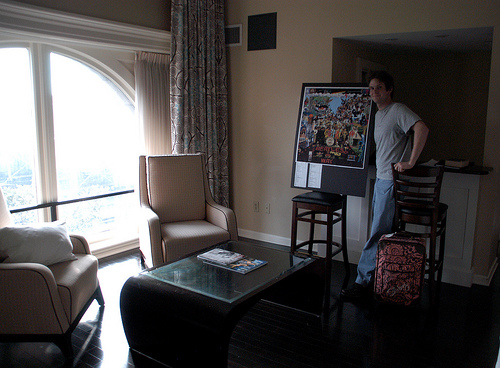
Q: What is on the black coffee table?
A: Glass top.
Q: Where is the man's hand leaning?
A: On the tall dark brown bar stool.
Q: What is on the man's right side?
A: Board with h picture on it.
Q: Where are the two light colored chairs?
A: On either side of the window.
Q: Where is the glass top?
A: On the coffee table.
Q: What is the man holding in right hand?
A: Piece of art.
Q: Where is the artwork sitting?
A: Left bar stool.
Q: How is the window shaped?
A: Semi-circle.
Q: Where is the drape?
A: Behind the right tan chair.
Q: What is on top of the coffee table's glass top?
A: Magazines.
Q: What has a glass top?
A: Coffee table.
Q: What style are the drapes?
A: Floor to ceiling.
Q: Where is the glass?
A: Covering the coffee table.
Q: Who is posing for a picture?
A: The man.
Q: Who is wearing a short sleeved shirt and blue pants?
A: A man.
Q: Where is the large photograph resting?
A: On a stool.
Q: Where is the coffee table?
A: In a room.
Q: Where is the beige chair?
A: In a room.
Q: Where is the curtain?
A: On a wall.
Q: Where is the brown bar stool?
A: Beside the counter.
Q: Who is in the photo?
A: A man in jeans.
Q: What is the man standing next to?
A: A painting.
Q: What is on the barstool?
A: Artwork.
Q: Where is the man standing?
A: Next to the artwork.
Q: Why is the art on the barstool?
A: To stand it up.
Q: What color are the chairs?
A: Beige.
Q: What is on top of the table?
A: Glass.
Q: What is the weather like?
A: Sunny.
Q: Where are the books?
A: On the coffee table.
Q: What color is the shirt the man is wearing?
A: Gray.